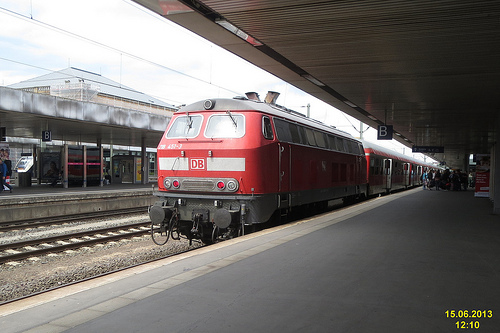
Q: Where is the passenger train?
A: At a station.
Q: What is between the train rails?
A: Gravel covered ground.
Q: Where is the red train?
A: At a station.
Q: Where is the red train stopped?
A: In the terminal.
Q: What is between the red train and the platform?
A: Railroad tracks.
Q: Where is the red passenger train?
A: At the station.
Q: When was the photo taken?
A: 06/15/2013.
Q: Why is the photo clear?
A: Its daytime.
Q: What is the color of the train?
A: Red.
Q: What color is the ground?
A: Grey.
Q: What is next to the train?
A: Tracks.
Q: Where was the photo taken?
A: At a train station.